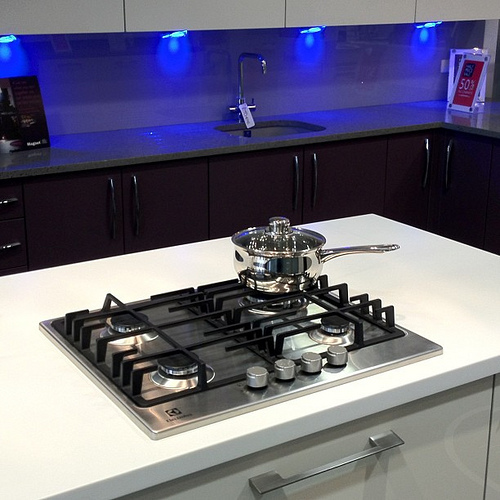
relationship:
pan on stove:
[223, 209, 408, 304] [26, 262, 453, 447]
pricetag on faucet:
[236, 103, 258, 139] [211, 43, 282, 148]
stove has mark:
[26, 262, 453, 447] [157, 406, 196, 427]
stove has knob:
[26, 262, 453, 447] [242, 367, 269, 392]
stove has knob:
[26, 262, 453, 447] [270, 352, 298, 380]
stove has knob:
[26, 262, 453, 447] [298, 347, 320, 377]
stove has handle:
[33, 273, 446, 440] [231, 426, 410, 499]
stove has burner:
[26, 262, 453, 447] [141, 349, 214, 392]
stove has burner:
[26, 262, 453, 447] [102, 304, 149, 334]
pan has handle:
[223, 209, 408, 304] [314, 230, 401, 266]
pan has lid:
[223, 209, 408, 304] [223, 211, 326, 259]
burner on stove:
[141, 349, 214, 392] [26, 262, 453, 447]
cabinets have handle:
[0, 122, 494, 269] [281, 146, 306, 209]